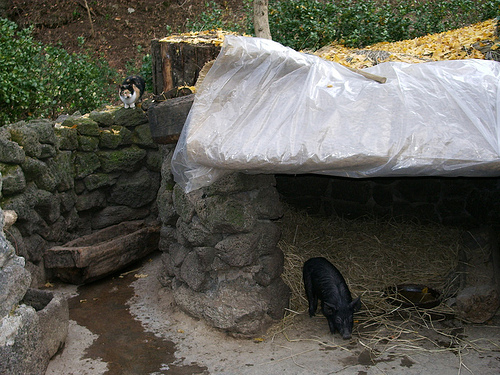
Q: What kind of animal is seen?
A: Pig.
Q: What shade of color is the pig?
A: Black.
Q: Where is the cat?
A: On the stone wall.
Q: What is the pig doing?
A: Standing in shelter.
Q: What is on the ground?
A: Water.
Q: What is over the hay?
A: Shelter.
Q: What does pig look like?
A: Dark.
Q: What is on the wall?
A: Cat.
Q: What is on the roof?
A: Plastic.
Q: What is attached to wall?
A: Water trough.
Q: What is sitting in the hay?
A: Water dish.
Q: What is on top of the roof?
A: Leaves.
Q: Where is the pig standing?
A: On hay.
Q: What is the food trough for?
A: The pig.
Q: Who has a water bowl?
A: The pig.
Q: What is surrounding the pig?
A: A rock wall.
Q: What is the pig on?
A: Hay.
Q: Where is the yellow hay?
A: Under the cave.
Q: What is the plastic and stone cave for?
A: Pig.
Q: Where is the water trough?
A: On the left.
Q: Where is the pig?
A: On the right.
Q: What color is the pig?
A: Black.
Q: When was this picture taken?
A: During the day.